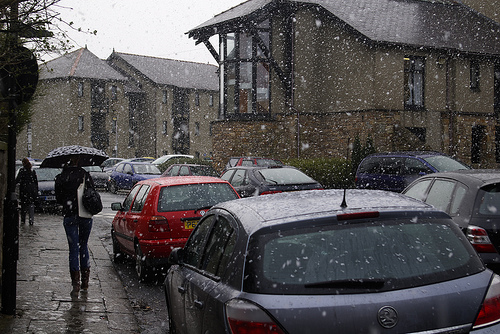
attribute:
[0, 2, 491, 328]
day — snowy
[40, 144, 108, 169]
umbrella — black, snowy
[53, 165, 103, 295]
woman — walking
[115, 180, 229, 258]
car — red, driven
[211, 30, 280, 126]
balcony — wooden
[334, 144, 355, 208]
antennae — black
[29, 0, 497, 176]
houses — here, divided, tan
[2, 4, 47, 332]
stop light — here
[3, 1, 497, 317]
snow — falling, here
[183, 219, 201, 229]
plate — hidden, yellow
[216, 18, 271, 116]
window — roofed, lit, large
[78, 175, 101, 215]
purse — black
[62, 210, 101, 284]
jeans — blue, black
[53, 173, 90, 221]
jacket — black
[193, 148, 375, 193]
bushes — growing